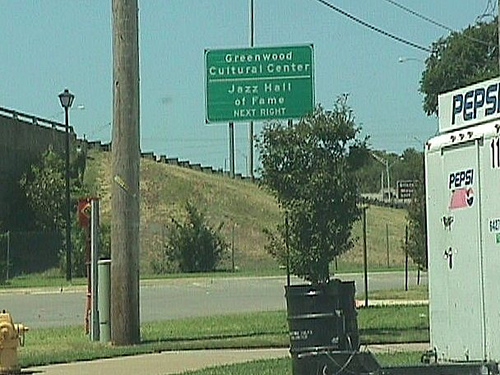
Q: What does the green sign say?
A: Greenwood Cultural Center Jazz hall of fame next right.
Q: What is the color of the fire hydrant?
A: Yellow.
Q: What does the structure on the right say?
A: Pepsi.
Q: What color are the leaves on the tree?
A: Green.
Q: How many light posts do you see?
A: One.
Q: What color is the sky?
A: Blue.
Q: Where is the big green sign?
A: By the road.